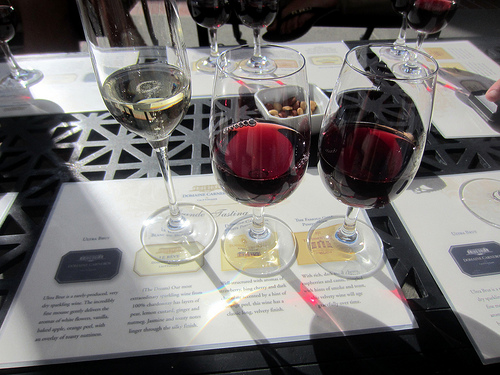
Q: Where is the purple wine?
A: In the glasses.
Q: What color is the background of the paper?
A: White.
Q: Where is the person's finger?
A: Near the upper right side.